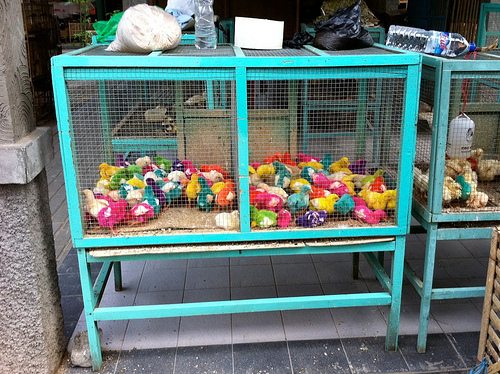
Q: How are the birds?
A: Caged.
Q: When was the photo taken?
A: Morning.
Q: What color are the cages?
A: Blue.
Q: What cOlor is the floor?
A: BLACK AND WHITE.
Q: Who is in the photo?
A: No one.